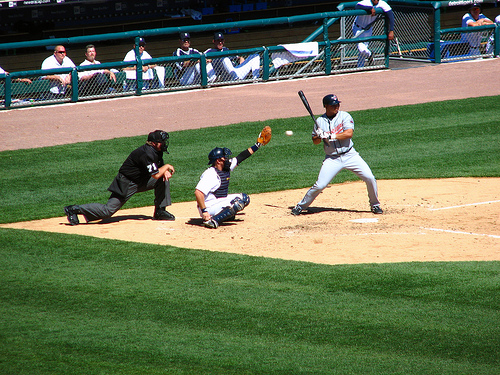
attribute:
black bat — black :
[289, 84, 328, 143]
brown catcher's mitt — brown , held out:
[255, 120, 274, 152]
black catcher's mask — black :
[204, 141, 244, 179]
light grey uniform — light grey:
[290, 111, 387, 230]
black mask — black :
[135, 120, 184, 161]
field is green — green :
[16, 73, 499, 313]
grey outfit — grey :
[286, 83, 420, 243]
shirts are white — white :
[33, 42, 81, 99]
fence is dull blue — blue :
[2, 4, 403, 93]